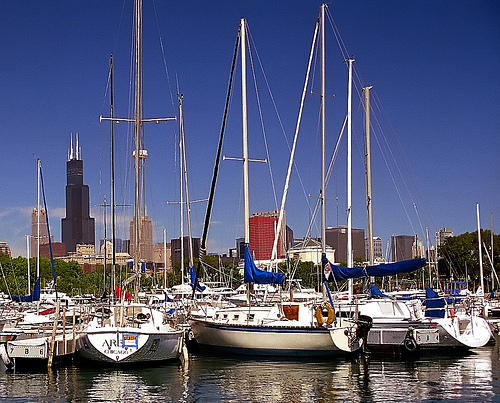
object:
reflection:
[86, 370, 161, 402]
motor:
[343, 313, 373, 351]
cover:
[241, 242, 290, 285]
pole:
[313, 0, 333, 298]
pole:
[363, 85, 379, 299]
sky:
[1, 0, 498, 267]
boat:
[79, 0, 190, 374]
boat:
[1, 322, 93, 374]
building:
[60, 129, 96, 254]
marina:
[2, 279, 494, 399]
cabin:
[265, 298, 317, 325]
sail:
[321, 255, 431, 283]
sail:
[191, 262, 206, 291]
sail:
[13, 279, 42, 301]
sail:
[488, 284, 498, 299]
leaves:
[4, 253, 18, 274]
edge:
[60, 217, 67, 244]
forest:
[2, 252, 181, 297]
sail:
[241, 242, 286, 285]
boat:
[186, 19, 368, 358]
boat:
[354, 82, 492, 356]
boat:
[468, 201, 500, 345]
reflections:
[234, 363, 442, 403]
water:
[9, 360, 499, 403]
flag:
[323, 261, 332, 281]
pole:
[335, 53, 363, 314]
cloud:
[0, 207, 160, 229]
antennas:
[69, 132, 74, 160]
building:
[247, 207, 281, 260]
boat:
[309, 296, 444, 359]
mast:
[229, 17, 254, 290]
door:
[284, 305, 299, 321]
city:
[0, 155, 500, 299]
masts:
[125, 2, 146, 291]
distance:
[13, 205, 465, 286]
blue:
[244, 246, 252, 282]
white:
[238, 14, 250, 265]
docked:
[188, 301, 376, 354]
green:
[8, 258, 20, 287]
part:
[22, 249, 81, 296]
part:
[6, 264, 80, 294]